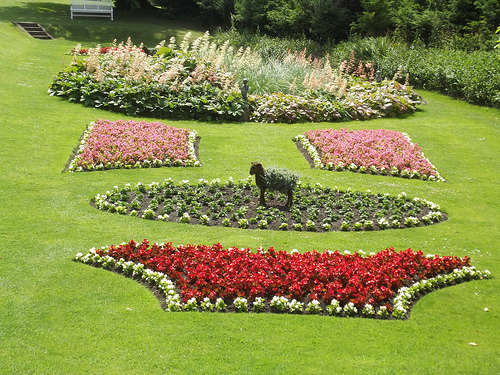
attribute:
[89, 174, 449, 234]
patch — round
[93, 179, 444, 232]
flowers — green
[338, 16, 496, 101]
shrubery — green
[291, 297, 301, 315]
flower — white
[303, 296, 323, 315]
flower — white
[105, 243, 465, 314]
flower — red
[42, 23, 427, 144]
flowers — white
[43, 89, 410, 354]
grass — green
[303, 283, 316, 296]
flower — red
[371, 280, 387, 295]
flower — red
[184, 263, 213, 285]
flowers — red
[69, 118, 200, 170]
flowers — pink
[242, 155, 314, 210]
animal — green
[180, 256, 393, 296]
flowers — red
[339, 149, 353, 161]
flower — pink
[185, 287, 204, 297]
flower — red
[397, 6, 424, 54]
trees — green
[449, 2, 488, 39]
trees — green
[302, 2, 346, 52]
trees — green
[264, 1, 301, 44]
trees — green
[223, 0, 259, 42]
trees — green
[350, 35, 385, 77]
bushes — green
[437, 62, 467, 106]
bushes — green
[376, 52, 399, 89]
bushes — green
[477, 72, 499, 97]
bushes — green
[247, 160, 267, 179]
head — brown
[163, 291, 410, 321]
flowers — white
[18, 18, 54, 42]
steps — cement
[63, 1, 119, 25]
bench — white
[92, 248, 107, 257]
flower — red